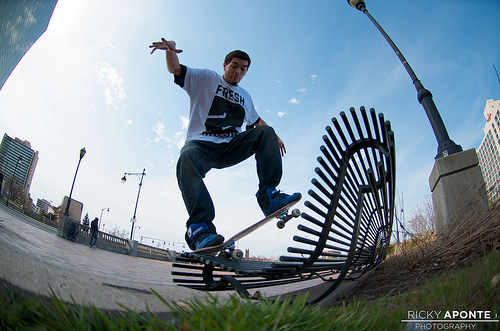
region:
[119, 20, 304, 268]
A person riding a skateboard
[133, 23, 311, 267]
A person doing a skateboard trick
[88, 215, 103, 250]
A person in the background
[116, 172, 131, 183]
Light bulb in the background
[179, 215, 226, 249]
A man's shoe on a skateboard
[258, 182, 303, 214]
A man's foot on a skateboard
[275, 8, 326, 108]
White clouds in a blue sky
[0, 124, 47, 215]
Building in the background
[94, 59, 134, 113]
Clouds in the sky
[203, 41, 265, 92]
head of a person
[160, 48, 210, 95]
arm of a person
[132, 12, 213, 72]
hand of a person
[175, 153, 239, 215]
leg of a person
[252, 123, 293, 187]
leg of a person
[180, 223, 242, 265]
feet of a person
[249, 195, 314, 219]
feet of a person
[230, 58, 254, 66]
eye of a person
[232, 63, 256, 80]
nose of a person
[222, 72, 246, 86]
mouth of a person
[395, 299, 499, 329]
photographer name in lower corner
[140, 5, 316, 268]
a guy on a skateboard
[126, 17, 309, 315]
guy doing trick on skateboard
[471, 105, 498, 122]
a red sign on a building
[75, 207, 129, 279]
a person on the sidewalk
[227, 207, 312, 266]
white wheels on skateboard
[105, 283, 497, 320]
grass by the bench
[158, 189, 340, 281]
blue shoes with white writing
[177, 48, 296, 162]
a black and white shirt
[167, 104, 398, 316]
metal bench made of bars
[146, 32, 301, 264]
guy on a skateboard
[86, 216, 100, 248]
person standing near railing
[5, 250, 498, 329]
green grass behind bench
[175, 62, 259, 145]
white and black shirt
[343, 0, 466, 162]
street light behind bench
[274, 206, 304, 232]
skateboard wheels in the air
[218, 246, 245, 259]
skateboard wheels on the bench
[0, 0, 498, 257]
mostly clear, blue sky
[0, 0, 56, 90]
clouds reflected on building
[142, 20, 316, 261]
a man on a skateboard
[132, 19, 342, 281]
a man doing trick on skateboard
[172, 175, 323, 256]
blue shoes on feet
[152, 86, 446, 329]
a curvy black bench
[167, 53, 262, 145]
white shirt with black writing on it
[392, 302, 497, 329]
photographer logo in corner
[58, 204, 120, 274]
a person walking on sidewalk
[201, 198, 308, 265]
white wheels on skateboard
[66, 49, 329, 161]
small white clouds in sky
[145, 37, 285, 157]
a black and white shirt